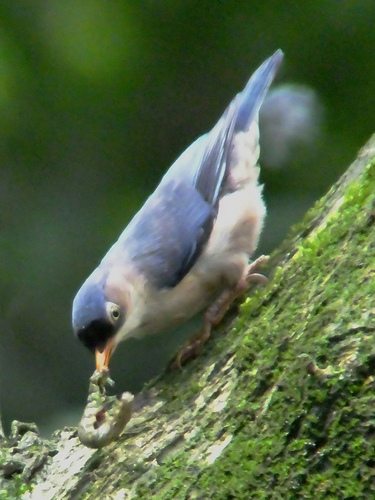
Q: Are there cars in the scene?
A: No, there are no cars.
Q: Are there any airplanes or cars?
A: No, there are no cars or airplanes.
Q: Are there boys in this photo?
A: No, there are no boys.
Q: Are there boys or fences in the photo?
A: No, there are no boys or fences.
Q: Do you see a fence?
A: No, there are no fences.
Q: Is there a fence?
A: No, there are no fences.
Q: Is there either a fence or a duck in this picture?
A: No, there are no fences or ducks.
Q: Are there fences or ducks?
A: No, there are no fences or ducks.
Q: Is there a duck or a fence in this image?
A: No, there are no fences or ducks.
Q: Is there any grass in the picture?
A: Yes, there is grass.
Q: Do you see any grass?
A: Yes, there is grass.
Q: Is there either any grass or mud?
A: Yes, there is grass.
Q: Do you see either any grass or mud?
A: Yes, there is grass.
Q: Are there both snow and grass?
A: No, there is grass but no snow.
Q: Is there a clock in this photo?
A: No, there are no clocks.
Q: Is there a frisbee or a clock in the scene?
A: No, there are no clocks or frisbees.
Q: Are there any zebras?
A: No, there are no zebras.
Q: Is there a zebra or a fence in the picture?
A: No, there are no zebras or fences.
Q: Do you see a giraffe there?
A: No, there are no giraffes.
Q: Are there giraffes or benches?
A: No, there are no giraffes or benches.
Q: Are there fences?
A: No, there are no fences.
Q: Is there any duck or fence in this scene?
A: No, there are no fences or ducks.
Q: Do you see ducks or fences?
A: No, there are no fences or ducks.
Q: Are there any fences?
A: No, there are no fences.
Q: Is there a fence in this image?
A: No, there are no fences.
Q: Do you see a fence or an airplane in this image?
A: No, there are no fences or airplanes.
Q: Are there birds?
A: Yes, there is a bird.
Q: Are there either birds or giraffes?
A: Yes, there is a bird.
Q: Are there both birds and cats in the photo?
A: No, there is a bird but no cats.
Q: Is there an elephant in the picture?
A: No, there are no elephants.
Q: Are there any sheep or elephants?
A: No, there are no elephants or sheep.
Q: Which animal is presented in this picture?
A: The animal is a bird.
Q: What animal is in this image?
A: The animal is a bird.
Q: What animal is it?
A: The animal is a bird.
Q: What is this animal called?
A: That is a bird.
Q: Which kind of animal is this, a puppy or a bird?
A: That is a bird.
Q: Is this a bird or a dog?
A: This is a bird.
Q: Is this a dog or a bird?
A: This is a bird.